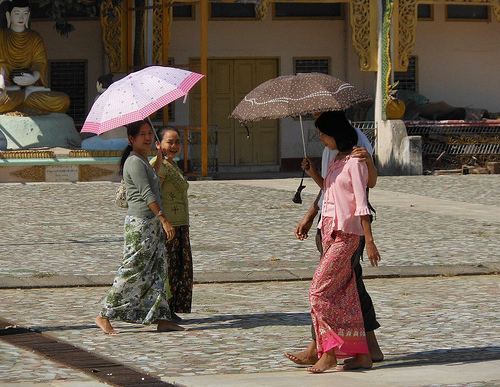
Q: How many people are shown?
A: 4.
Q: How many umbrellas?
A: 2.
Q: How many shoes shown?
A: 0.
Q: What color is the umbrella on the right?
A: Brown.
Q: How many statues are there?
A: 1.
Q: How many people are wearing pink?
A: 1.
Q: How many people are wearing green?
A: 2.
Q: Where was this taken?
A: On a street.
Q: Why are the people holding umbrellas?
A: For shade.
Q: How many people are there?
A: 4.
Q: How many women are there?
A: 3.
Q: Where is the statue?
A: In front of the building.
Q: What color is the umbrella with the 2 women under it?
A: Pink.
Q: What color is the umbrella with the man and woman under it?
A: Brown.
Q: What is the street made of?
A: Bricks.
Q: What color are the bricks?
A: Brown.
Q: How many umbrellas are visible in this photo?
A: Two.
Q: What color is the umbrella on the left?
A: Pink and white.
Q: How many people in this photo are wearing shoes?
A: None.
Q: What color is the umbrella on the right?
A: Brown and white.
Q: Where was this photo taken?
A: In the street, near buildings.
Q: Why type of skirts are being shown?
A: Patterned skirts.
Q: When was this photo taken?
A: Outside, during the daytime.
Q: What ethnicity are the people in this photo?
A: Asian.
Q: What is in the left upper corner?
A: A statue.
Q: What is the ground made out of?
A: Bricks.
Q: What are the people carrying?
A: Umbrellas.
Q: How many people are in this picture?
A: Four.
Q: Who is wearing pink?
A: The woman on the right.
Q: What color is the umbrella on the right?
A: Brown.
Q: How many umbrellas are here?
A: Two.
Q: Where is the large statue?
A: Against the building, on the left side.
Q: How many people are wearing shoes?
A: None.